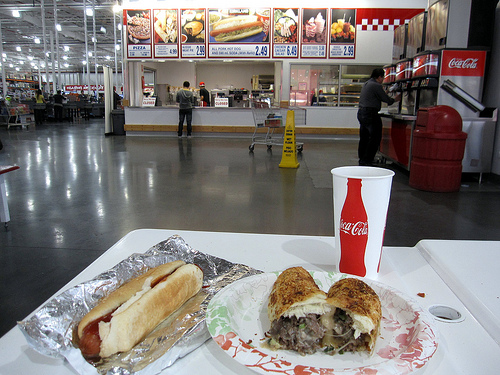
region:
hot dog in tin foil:
[51, 237, 215, 366]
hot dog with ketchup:
[68, 248, 235, 356]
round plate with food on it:
[224, 252, 424, 368]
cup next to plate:
[322, 151, 405, 243]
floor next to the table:
[90, 146, 178, 208]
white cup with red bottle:
[301, 161, 391, 265]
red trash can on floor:
[395, 98, 480, 180]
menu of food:
[161, 18, 290, 61]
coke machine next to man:
[371, 46, 464, 103]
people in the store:
[16, 63, 81, 126]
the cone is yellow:
[269, 111, 321, 180]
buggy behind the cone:
[247, 96, 322, 176]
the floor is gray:
[77, 171, 251, 221]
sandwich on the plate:
[238, 278, 397, 373]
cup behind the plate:
[325, 169, 400, 267]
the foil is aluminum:
[160, 316, 210, 353]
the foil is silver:
[162, 321, 218, 358]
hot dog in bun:
[70, 264, 215, 349]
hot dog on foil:
[67, 242, 236, 371]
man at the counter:
[155, 83, 220, 135]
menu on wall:
[120, 7, 357, 62]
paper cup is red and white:
[338, 158, 403, 305]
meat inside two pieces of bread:
[264, 259, 385, 368]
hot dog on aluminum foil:
[58, 223, 200, 372]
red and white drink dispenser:
[380, 36, 481, 130]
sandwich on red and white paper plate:
[216, 262, 425, 372]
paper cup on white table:
[330, 154, 407, 310]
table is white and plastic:
[141, 208, 487, 372]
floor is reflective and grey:
[40, 127, 217, 234]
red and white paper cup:
[333, 146, 391, 266]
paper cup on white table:
[326, 161, 379, 275]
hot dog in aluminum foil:
[94, 227, 204, 362]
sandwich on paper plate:
[277, 276, 379, 354]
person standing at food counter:
[166, 71, 195, 127]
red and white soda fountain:
[375, 42, 475, 117]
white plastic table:
[129, 212, 449, 374]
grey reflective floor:
[22, 106, 173, 241]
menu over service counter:
[129, 3, 364, 62]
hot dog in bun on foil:
[12, 228, 268, 373]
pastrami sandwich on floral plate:
[206, 261, 439, 370]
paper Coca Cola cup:
[328, 165, 394, 280]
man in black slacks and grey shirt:
[348, 65, 398, 168]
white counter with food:
[1, 227, 498, 374]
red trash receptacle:
[402, 104, 470, 197]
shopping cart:
[246, 97, 307, 160]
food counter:
[115, 1, 470, 144]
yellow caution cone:
[275, 106, 305, 171]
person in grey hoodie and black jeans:
[170, 79, 200, 140]